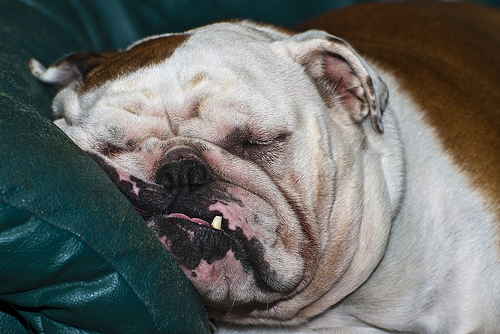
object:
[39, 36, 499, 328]
nose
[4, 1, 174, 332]
cushion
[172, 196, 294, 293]
lip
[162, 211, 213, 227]
tongue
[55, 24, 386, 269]
wall decoration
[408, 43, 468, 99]
fur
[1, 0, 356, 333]
pillow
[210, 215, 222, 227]
tooth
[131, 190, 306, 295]
mouth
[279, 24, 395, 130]
ear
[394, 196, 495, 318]
fur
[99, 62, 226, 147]
furrow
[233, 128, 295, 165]
eye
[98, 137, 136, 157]
eye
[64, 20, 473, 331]
dog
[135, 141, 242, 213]
nose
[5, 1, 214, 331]
couch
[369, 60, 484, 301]
fur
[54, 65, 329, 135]
forehead